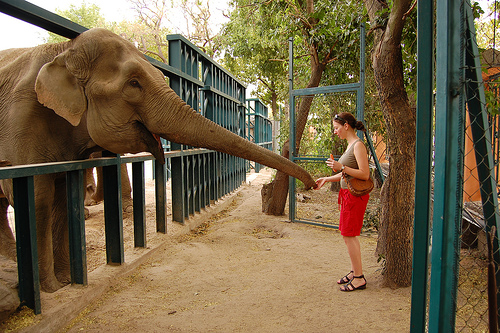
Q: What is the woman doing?
A: Feeding an elephant.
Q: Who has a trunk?
A: Elephant.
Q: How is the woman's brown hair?
A: In a bun.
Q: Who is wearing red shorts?
A: The woman.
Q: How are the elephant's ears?
A: Big.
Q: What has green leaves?
A: The trees.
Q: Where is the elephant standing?
A: In the dirt.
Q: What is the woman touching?
A: Elephant trunk.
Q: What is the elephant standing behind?
A: Fence.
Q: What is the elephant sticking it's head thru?
A: Fence.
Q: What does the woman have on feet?
A: Sandals.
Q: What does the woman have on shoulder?
A: Purse.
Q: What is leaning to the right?
A: Tree.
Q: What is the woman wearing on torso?
A: Brown tank top.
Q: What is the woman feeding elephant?
A: Carrots.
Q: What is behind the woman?
A: Fence.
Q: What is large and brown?
A: Elephant.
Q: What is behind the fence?
A: Elephant.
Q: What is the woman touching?
A: Elephant trunk.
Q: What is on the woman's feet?
A: Sandals.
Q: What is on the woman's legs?
A: Red shorts.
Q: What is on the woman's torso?
A: Brown tank top.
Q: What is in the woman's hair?
A: Ponytail.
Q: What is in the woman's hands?
A: Carrots.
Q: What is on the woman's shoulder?
A: Purse.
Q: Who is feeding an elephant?
A: A woman.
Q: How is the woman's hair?
A: In a bun.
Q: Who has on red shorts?
A: The woman.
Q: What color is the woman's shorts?
A: Red.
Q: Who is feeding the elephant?
A: The woman.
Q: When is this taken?
A: Daytime.